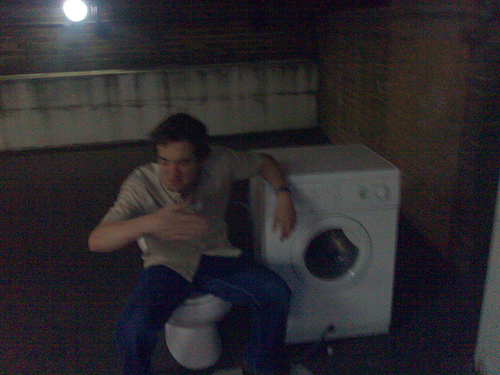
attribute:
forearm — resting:
[259, 156, 292, 196]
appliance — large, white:
[246, 141, 406, 340]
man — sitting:
[87, 110, 301, 375]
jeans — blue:
[112, 251, 296, 375]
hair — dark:
[149, 112, 210, 160]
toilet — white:
[165, 286, 236, 370]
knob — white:
[374, 185, 390, 200]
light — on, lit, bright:
[61, 1, 92, 24]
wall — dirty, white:
[4, 56, 322, 149]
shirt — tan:
[97, 144, 266, 284]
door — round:
[291, 219, 372, 288]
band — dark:
[271, 183, 287, 191]